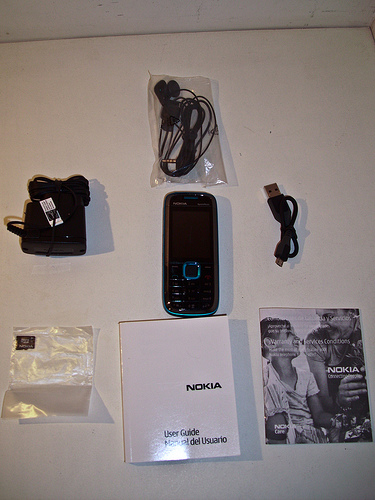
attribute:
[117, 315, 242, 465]
user guide — white, booklet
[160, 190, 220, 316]
phone — nokia, rectangle, mobile, black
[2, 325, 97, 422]
bag — plastic, clear, empty, polythene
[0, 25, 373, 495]
table — white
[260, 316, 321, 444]
person — talking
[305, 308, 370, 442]
person — talking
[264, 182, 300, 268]
connector — usb cable, black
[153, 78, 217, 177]
earphones — present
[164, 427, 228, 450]
writing — black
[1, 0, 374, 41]
wall — present, white